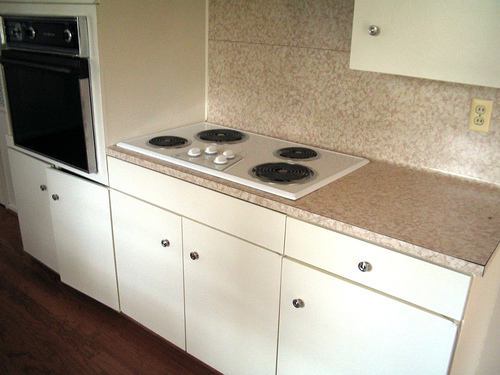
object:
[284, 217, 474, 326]
drawer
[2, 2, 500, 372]
kitchen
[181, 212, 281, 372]
cabinets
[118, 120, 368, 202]
cook top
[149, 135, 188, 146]
burners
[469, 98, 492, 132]
outlet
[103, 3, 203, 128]
wall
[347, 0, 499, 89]
cabinet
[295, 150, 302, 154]
eye on stove top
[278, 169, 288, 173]
eye on stove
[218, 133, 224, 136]
an eye on stove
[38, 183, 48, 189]
knob on cabinet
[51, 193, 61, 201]
knob on cabinet door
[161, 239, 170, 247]
knob on cabinet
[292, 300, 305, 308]
knob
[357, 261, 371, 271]
on cabinet door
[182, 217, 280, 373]
cabinet door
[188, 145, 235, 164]
four white dials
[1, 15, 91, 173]
black oven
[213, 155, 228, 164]
dials on oven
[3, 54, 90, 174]
chrome oven doors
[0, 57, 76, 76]
oven handle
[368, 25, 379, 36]
single knob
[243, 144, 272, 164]
stove is white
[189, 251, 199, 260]
round silver knobs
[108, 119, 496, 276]
tan counter top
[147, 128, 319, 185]
four burners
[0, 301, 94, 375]
floor is dark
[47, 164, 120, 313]
door is not closed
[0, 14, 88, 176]
black front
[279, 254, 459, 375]
white cabinets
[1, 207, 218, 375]
wooden floor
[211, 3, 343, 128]
tan wall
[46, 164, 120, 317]
cabinet open